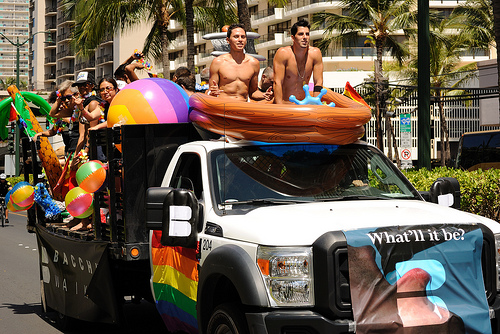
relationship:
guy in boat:
[274, 18, 327, 107] [187, 84, 368, 144]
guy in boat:
[207, 21, 274, 97] [187, 84, 368, 144]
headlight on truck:
[257, 242, 317, 309] [23, 128, 488, 328]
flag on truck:
[121, 224, 211, 295] [122, 71, 387, 312]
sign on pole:
[400, 116, 412, 144] [403, 111, 408, 170]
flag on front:
[147, 224, 200, 331] [306, 222, 499, 329]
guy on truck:
[274, 18, 327, 107] [23, 128, 488, 328]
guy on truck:
[207, 21, 274, 97] [23, 128, 488, 328]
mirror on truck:
[139, 185, 200, 245] [11, 12, 499, 332]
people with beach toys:
[44, 65, 149, 140] [5, 80, 187, 228]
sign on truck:
[58, 122, 263, 307] [23, 128, 488, 328]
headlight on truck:
[267, 247, 316, 278] [11, 12, 499, 332]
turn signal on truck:
[256, 256, 271, 277] [23, 100, 498, 332]